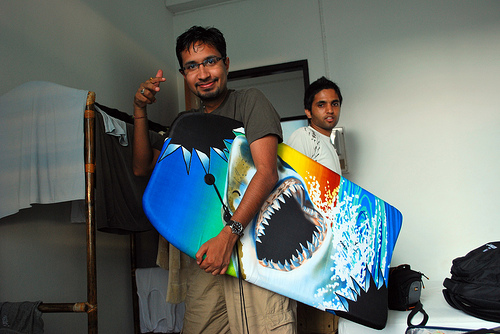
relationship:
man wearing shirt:
[259, 68, 396, 330] [285, 125, 348, 176]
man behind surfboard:
[259, 68, 396, 330] [137, 108, 404, 329]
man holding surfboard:
[131, 25, 298, 334] [137, 108, 404, 329]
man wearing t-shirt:
[131, 25, 298, 334] [177, 85, 282, 140]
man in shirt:
[282, 77, 342, 334] [288, 127, 348, 174]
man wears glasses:
[131, 25, 298, 334] [179, 57, 226, 73]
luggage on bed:
[356, 220, 498, 327] [350, 288, 497, 332]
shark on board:
[221, 134, 333, 294] [135, 109, 403, 321]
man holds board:
[131, 25, 298, 334] [136, 109, 404, 330]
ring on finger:
[139, 84, 146, 96] [153, 77, 168, 83]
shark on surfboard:
[247, 173, 324, 292] [148, 152, 367, 316]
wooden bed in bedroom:
[0, 75, 166, 332] [0, 4, 498, 331]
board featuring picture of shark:
[135, 109, 403, 321] [217, 186, 346, 298]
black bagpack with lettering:
[441, 237, 498, 325] [484, 245, 485, 252]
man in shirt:
[131, 25, 298, 334] [192, 81, 284, 148]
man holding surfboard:
[131, 25, 298, 334] [141, 116, 418, 326]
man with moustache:
[135, 28, 282, 331] [192, 74, 222, 88]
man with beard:
[135, 28, 282, 331] [187, 85, 230, 100]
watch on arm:
[223, 216, 245, 238] [194, 121, 282, 279]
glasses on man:
[179, 55, 221, 75] [173, 23, 284, 153]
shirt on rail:
[131, 267, 187, 331] [35, 300, 87, 314]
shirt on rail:
[92, 103, 131, 150] [35, 300, 87, 314]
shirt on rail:
[87, 113, 164, 234] [35, 300, 87, 314]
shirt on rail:
[0, 298, 47, 332] [35, 300, 87, 314]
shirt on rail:
[0, 77, 90, 219] [35, 300, 87, 314]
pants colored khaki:
[184, 243, 299, 332] [186, 264, 225, 332]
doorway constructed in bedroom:
[226, 57, 308, 114] [0, 0, 497, 334]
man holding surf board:
[131, 25, 298, 334] [140, 108, 403, 329]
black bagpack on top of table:
[441, 237, 498, 325] [426, 304, 468, 332]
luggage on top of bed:
[387, 264, 428, 327] [337, 288, 497, 334]